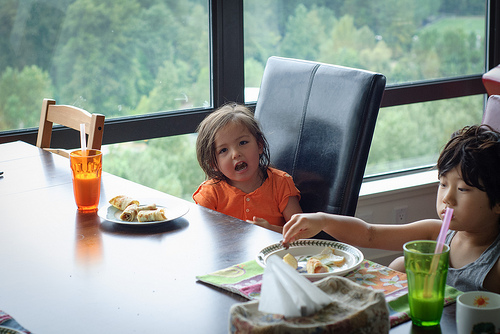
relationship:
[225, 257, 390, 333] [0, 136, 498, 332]
box on table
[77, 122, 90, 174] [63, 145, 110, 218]
straw in drink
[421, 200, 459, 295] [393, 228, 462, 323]
straw in drink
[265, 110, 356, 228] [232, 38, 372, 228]
reflection on seat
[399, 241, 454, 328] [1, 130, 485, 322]
glass on table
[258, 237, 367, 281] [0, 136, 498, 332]
plate on table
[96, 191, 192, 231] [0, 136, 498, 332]
plate on table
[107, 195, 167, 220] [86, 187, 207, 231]
finger foods on plate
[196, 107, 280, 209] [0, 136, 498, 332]
child seated at table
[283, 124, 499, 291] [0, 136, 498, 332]
boy seated at table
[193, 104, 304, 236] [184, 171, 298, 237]
child wearing shirt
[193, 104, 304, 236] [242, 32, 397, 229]
child in chair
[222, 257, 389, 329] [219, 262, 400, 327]
box with cover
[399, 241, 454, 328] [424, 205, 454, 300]
glass with straw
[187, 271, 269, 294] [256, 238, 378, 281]
placemat under dinner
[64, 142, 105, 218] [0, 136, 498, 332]
glass on table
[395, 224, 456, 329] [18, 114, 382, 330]
glass on table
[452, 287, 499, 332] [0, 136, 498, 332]
coffee mug on table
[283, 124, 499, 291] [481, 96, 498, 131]
boy on chair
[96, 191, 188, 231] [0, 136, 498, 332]
plate on table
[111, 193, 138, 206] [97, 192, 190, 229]
pancake on plate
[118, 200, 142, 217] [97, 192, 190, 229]
pancake on plate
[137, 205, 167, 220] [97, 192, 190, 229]
pancake on plate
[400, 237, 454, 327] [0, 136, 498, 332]
cup on table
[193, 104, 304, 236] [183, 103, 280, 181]
child has head